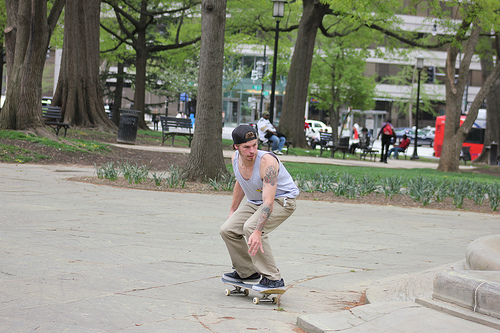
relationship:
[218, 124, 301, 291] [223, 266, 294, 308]
man riding skateboard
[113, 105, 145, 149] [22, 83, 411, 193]
trash can in park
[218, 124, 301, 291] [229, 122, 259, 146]
man wearing hat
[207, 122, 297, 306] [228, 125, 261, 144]
man wearing hat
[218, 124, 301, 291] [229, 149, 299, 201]
man wearing top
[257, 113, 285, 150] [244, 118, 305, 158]
person sitting on bench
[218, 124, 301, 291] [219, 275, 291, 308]
man riding skate board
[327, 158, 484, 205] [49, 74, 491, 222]
plants planted in park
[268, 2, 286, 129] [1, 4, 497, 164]
lamp in park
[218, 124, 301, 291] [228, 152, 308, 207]
man in top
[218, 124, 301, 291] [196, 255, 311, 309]
man riding skateboard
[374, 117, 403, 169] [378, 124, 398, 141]
person wearing backpack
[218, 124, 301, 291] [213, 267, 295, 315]
man on board